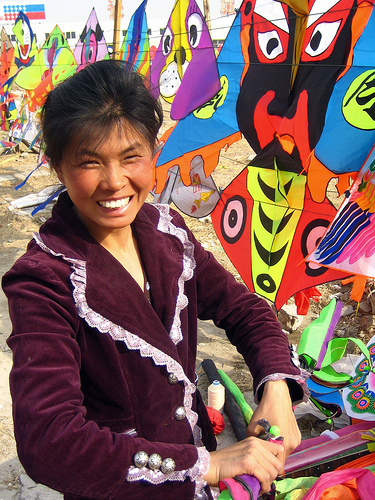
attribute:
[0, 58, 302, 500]
woman — smiling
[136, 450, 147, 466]
button — grey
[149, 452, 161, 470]
button — grey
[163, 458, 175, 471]
button — grey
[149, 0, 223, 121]
kite —  shape of dog, yellow, hanged, dog face,  like puppy,  of dog whispers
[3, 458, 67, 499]
shadow — cast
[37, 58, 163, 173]
hair — black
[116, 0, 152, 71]
kite — blue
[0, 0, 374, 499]
scene — daytime, outdoor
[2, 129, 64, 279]
sand — brown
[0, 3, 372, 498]
picture — daytime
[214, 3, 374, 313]
view —  of evil,  artistic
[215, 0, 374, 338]
mural — colorful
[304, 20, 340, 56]
eye — slanted